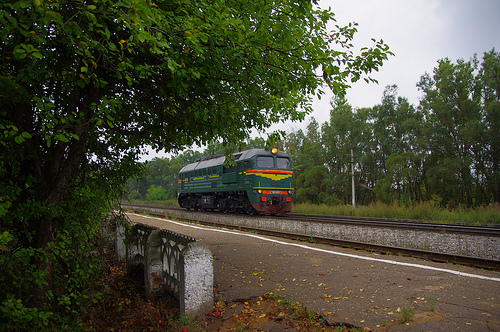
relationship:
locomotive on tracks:
[177, 148, 294, 216] [315, 205, 383, 238]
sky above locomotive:
[369, 7, 475, 51] [177, 148, 294, 216]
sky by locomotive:
[369, 7, 475, 51] [177, 148, 294, 216]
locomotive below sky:
[177, 148, 294, 216] [369, 7, 475, 51]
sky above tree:
[369, 7, 475, 51] [375, 90, 464, 165]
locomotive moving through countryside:
[170, 134, 304, 219] [7, 29, 497, 327]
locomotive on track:
[177, 148, 294, 216] [126, 202, 497, 280]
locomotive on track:
[177, 148, 294, 216] [111, 198, 489, 282]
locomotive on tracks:
[177, 148, 294, 216] [115, 196, 497, 290]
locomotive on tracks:
[177, 148, 294, 216] [109, 194, 498, 279]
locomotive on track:
[177, 148, 294, 216] [126, 208, 500, 269]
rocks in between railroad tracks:
[115, 199, 496, 269] [107, 192, 497, 275]